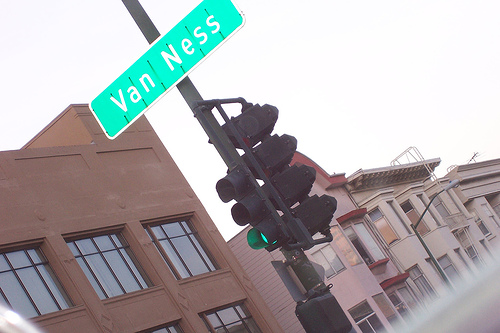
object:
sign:
[85, 0, 247, 141]